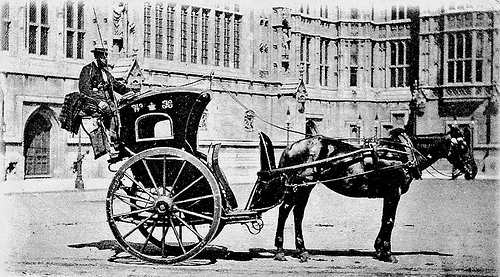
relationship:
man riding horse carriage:
[79, 48, 142, 141] [114, 89, 478, 263]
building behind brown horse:
[0, 0, 499, 181] [273, 123, 478, 262]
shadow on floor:
[193, 236, 497, 268] [0, 177, 497, 277]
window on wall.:
[25, 2, 51, 56] [195, 47, 285, 154]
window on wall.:
[64, 1, 85, 62] [195, 47, 285, 154]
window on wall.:
[142, 3, 154, 60] [195, 47, 285, 154]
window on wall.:
[210, 8, 223, 69] [195, 47, 285, 154]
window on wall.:
[228, 10, 241, 71] [195, 47, 285, 154]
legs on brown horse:
[271, 178, 318, 263] [273, 123, 478, 262]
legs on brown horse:
[373, 192, 400, 262] [273, 123, 478, 262]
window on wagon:
[135, 113, 174, 142] [85, 86, 285, 270]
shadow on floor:
[66, 239, 454, 267] [0, 174, 498, 274]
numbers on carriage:
[124, 90, 181, 122] [89, 79, 283, 269]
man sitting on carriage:
[79, 47, 132, 137] [100, 91, 419, 263]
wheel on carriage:
[104, 144, 224, 262] [54, 86, 290, 270]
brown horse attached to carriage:
[273, 123, 478, 262] [98, 85, 243, 266]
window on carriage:
[135, 110, 179, 144] [100, 91, 419, 263]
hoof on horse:
[369, 246, 403, 267] [264, 112, 487, 272]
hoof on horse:
[294, 249, 315, 266] [264, 112, 487, 272]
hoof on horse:
[272, 248, 286, 262] [264, 112, 487, 272]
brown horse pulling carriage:
[273, 123, 478, 262] [70, 90, 285, 257]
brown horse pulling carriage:
[273, 123, 478, 262] [104, 86, 271, 264]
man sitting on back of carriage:
[79, 48, 142, 141] [99, 71, 451, 261]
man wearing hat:
[79, 48, 142, 141] [89, 42, 110, 53]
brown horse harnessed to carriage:
[273, 123, 478, 262] [99, 71, 451, 261]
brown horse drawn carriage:
[273, 123, 478, 262] [59, 70, 477, 264]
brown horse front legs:
[273, 123, 478, 262] [357, 192, 424, 270]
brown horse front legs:
[273, 123, 478, 262] [370, 198, 405, 258]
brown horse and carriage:
[272, 117, 489, 266] [99, 71, 451, 261]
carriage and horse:
[104, 86, 271, 264] [271, 111, 478, 267]